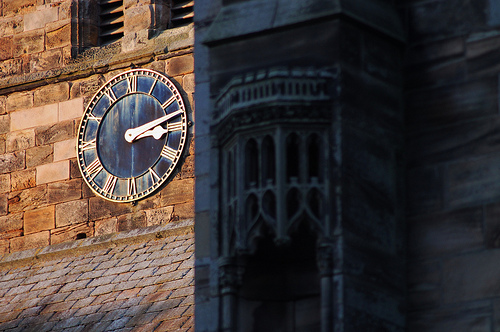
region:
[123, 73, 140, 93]
roman numeral on clock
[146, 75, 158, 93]
roman numeral on clock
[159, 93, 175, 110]
roman numeral on clock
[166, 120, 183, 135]
roman numeral on clock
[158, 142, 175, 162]
roman numeral on clock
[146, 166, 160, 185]
roman numeral on clock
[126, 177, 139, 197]
roman numeral on clock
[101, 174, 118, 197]
roman numeral on clock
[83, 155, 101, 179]
roman numeral on clock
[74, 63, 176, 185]
clock on side of wall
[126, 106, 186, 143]
hands of clock are white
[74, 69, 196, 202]
roman numerals on the clock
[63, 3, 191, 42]
two windows on the wall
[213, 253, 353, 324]
entrance to the building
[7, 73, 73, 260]
wall of buiding is made of bricks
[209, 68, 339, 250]
overhead of entrance is gated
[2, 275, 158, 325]
sun reflection on the roof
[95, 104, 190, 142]
time shows is 3:13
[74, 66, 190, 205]
A clock with a black face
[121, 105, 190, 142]
Two hands of a clock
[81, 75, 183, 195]
Golden numbers on a clock face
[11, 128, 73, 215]
A wall of red bricks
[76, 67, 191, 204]
A clock face on a brick wall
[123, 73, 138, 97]
"12" in roman numerals on a clock face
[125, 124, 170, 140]
An hour hand pointed at "3"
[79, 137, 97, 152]
A sideways "9" in roman numerals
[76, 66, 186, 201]
A black clock face with gold accent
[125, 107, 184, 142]
A minute hand covers part of the hour hand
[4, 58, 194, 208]
a clock on a large church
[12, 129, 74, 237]
the brick wall of a church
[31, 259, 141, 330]
a bunch of shingles on a roof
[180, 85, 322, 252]
the small window of a church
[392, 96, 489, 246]
gray bricks on a roof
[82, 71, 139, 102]
roman numerals on a clock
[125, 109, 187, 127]
the long minute hand on a clock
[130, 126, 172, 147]
the small hour hand on a clock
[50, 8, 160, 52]
two small windows with shutters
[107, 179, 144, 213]
the border of a large clock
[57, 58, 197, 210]
large clock with gold accents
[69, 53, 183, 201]
clock with roman numeral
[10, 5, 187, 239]
brown brick building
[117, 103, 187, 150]
gold hands on clock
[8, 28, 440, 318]
part of the building in sun light and part in shade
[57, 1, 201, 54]
brown shutters on windows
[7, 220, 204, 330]
brown shingles on roof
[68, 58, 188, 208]
gold roman numerals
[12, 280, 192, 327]
shadow cast on roof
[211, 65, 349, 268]
decorative area above window